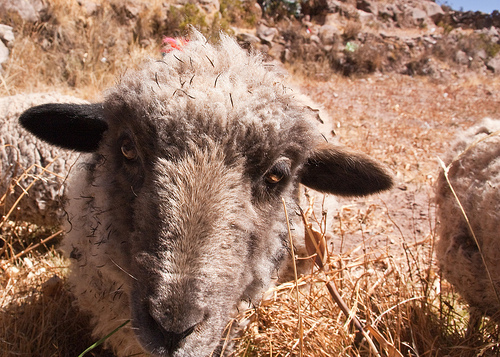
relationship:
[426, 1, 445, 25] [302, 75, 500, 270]
rock on ground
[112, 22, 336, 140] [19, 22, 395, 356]
fur on sheep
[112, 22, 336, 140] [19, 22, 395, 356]
fur on face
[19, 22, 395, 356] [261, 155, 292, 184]
sheep has eye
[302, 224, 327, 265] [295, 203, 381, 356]
leaf on branch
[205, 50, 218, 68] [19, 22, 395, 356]
strand on sheep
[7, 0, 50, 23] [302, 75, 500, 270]
rock on ground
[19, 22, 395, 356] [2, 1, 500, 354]
sheep in field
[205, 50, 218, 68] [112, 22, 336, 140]
strand in fur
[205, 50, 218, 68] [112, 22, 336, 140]
debris in fur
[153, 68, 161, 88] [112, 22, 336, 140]
debris in fur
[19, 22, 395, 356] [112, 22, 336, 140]
sheep has fur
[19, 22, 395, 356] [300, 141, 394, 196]
sheep has ear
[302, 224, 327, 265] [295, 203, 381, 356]
leaf on stick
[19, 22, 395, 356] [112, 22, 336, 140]
head has fur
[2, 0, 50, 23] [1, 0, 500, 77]
rock on hillside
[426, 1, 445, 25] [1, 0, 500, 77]
rock on hillside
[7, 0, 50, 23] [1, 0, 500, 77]
rock on hillside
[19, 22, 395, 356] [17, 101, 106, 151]
sheep has ear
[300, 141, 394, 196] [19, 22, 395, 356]
ear out of sheep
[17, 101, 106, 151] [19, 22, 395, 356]
ear out of sheep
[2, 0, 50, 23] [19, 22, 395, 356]
rock behind sheep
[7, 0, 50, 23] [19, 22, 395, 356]
rock behind sheep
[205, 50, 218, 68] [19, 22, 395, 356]
grass on sheep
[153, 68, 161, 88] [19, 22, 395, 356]
debris on sheep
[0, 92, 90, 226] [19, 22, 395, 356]
sheep by sheep